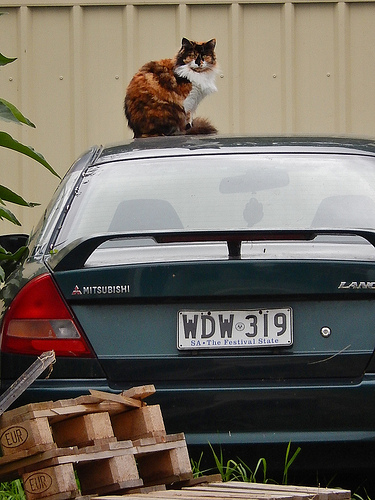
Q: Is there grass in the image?
A: Yes, there is grass.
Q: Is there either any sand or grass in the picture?
A: Yes, there is grass.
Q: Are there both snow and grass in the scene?
A: No, there is grass but no snow.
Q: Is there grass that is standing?
A: Yes, there is grass that is standing.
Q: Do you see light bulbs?
A: No, there are no light bulbs.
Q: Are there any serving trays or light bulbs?
A: No, there are no light bulbs or serving trays.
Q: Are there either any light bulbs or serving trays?
A: No, there are no light bulbs or serving trays.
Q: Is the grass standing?
A: Yes, the grass is standing.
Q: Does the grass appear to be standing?
A: Yes, the grass is standing.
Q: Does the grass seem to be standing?
A: Yes, the grass is standing.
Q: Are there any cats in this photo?
A: Yes, there is a cat.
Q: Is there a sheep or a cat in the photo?
A: Yes, there is a cat.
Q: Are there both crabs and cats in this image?
A: No, there is a cat but no crabs.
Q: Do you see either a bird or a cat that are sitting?
A: Yes, the cat is sitting.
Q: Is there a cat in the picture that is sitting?
A: Yes, there is a cat that is sitting.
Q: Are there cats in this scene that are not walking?
A: Yes, there is a cat that is sitting.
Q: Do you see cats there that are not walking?
A: Yes, there is a cat that is sitting .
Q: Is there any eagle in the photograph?
A: No, there are no eagles.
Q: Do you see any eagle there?
A: No, there are no eagles.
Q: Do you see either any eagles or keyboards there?
A: No, there are no eagles or keyboards.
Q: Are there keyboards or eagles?
A: No, there are no eagles or keyboards.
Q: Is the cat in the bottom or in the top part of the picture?
A: The cat is in the top of the image.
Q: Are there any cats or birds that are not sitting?
A: No, there is a cat but it is sitting.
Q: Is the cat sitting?
A: Yes, the cat is sitting.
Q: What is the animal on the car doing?
A: The cat is sitting.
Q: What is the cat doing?
A: The cat is sitting.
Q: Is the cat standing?
A: No, the cat is sitting.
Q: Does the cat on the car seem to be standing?
A: No, the cat is sitting.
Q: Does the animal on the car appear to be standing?
A: No, the cat is sitting.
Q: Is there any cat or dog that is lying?
A: No, there is a cat but it is sitting.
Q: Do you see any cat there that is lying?
A: No, there is a cat but it is sitting.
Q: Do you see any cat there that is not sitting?
A: No, there is a cat but it is sitting.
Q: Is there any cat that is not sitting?
A: No, there is a cat but it is sitting.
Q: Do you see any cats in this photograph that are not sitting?
A: No, there is a cat but it is sitting.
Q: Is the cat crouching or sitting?
A: The cat is sitting.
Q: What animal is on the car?
A: The animal is a cat.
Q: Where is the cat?
A: The cat is on the car.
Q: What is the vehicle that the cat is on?
A: The vehicle is a car.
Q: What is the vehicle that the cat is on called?
A: The vehicle is a car.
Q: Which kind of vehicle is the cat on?
A: The cat is on the car.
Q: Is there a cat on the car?
A: Yes, there is a cat on the car.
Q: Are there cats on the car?
A: Yes, there is a cat on the car.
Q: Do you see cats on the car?
A: Yes, there is a cat on the car.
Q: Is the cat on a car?
A: Yes, the cat is on a car.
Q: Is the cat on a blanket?
A: No, the cat is on a car.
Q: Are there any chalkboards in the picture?
A: No, there are no chalkboards.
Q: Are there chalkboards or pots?
A: No, there are no chalkboards or pots.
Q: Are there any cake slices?
A: No, there are no cake slices.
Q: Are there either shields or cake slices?
A: No, there are no cake slices or shields.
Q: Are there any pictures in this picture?
A: No, there are no pictures.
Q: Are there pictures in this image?
A: No, there are no pictures.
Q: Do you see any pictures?
A: No, there are no pictures.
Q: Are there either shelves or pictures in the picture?
A: No, there are no pictures or shelves.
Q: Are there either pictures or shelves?
A: No, there are no pictures or shelves.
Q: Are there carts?
A: No, there are no carts.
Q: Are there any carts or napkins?
A: No, there are no carts or napkins.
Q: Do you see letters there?
A: Yes, there are letters.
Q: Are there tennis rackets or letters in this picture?
A: Yes, there are letters.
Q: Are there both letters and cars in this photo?
A: Yes, there are both letters and a car.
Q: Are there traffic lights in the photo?
A: No, there are no traffic lights.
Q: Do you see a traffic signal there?
A: No, there are no traffic lights.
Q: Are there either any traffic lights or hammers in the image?
A: No, there are no traffic lights or hammers.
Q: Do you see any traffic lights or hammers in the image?
A: No, there are no traffic lights or hammers.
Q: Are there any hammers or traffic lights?
A: No, there are no traffic lights or hammers.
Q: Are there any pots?
A: No, there are no pots.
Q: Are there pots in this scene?
A: No, there are no pots.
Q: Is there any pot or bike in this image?
A: No, there are no pots or bikes.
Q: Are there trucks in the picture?
A: No, there are no trucks.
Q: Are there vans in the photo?
A: No, there are no vans.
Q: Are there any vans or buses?
A: No, there are no vans or buses.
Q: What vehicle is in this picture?
A: The vehicle is a car.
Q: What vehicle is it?
A: The vehicle is a car.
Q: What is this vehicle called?
A: This is a car.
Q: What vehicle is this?
A: This is a car.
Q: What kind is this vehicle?
A: This is a car.